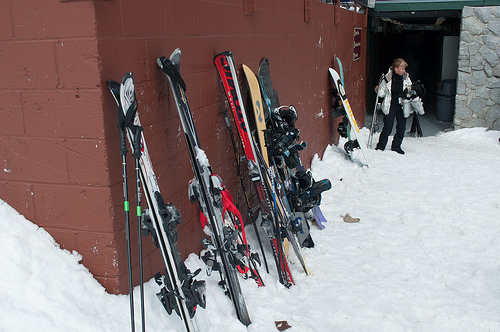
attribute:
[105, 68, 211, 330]
skis — white, black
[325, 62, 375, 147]
surfboard — white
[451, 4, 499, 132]
wall — stone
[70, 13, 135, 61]
brick — red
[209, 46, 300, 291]
ski — red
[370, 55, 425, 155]
woman — black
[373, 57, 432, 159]
woman — black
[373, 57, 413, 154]
woman — old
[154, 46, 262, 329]
skis — black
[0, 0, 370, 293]
wall — red, concrete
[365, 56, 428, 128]
coat — black and white